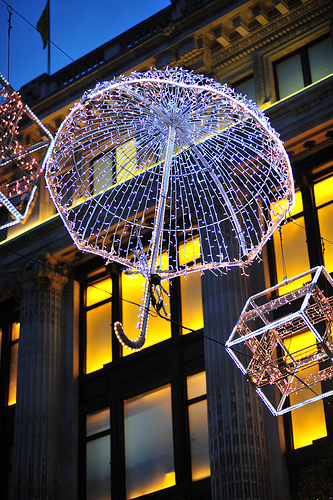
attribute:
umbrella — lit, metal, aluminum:
[46, 66, 296, 347]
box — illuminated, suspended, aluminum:
[224, 266, 332, 415]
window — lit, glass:
[77, 272, 120, 374]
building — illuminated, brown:
[2, 0, 331, 499]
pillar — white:
[11, 250, 69, 500]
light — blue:
[53, 21, 168, 90]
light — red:
[2, 85, 46, 200]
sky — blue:
[0, 0, 171, 103]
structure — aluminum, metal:
[0, 67, 53, 230]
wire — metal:
[2, 242, 332, 422]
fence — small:
[1, 6, 174, 110]